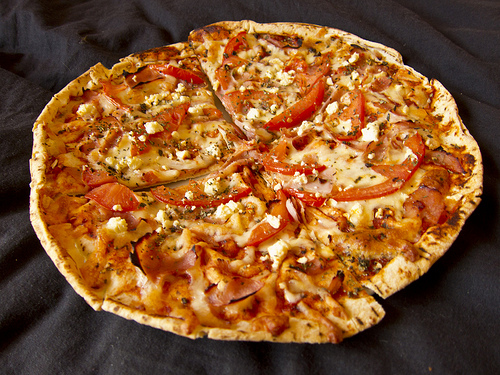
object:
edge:
[278, 21, 320, 34]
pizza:
[25, 19, 486, 346]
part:
[460, 1, 493, 37]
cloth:
[484, 71, 499, 141]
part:
[247, 79, 273, 100]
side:
[23, 188, 115, 306]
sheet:
[10, 8, 49, 32]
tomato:
[152, 64, 203, 86]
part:
[463, 262, 480, 275]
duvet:
[358, 335, 441, 360]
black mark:
[131, 253, 139, 266]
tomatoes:
[265, 81, 325, 132]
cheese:
[319, 153, 326, 160]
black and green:
[158, 141, 167, 157]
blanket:
[38, 3, 164, 17]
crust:
[372, 262, 423, 299]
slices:
[24, 41, 250, 188]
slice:
[185, 17, 403, 144]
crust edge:
[187, 21, 232, 38]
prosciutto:
[141, 279, 173, 301]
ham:
[405, 186, 445, 223]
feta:
[144, 121, 164, 133]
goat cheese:
[109, 222, 118, 226]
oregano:
[342, 242, 375, 275]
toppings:
[254, 188, 263, 199]